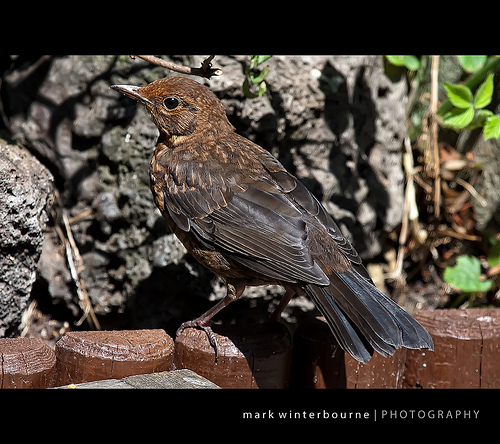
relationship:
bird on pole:
[103, 73, 437, 366] [182, 324, 289, 388]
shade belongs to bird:
[218, 308, 330, 386] [103, 73, 437, 366]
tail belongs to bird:
[309, 277, 436, 356] [103, 73, 437, 366]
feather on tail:
[344, 335, 447, 364] [309, 277, 436, 356]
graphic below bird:
[240, 401, 489, 433] [103, 73, 437, 366]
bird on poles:
[103, 73, 437, 366] [2, 302, 499, 384]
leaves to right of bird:
[386, 59, 499, 140] [103, 73, 437, 366]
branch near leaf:
[133, 54, 223, 78] [249, 54, 272, 94]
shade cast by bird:
[218, 308, 330, 386] [103, 73, 437, 366]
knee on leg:
[225, 281, 247, 301] [170, 288, 245, 356]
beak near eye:
[110, 81, 143, 97] [162, 98, 183, 109]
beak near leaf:
[110, 81, 143, 97] [249, 54, 272, 94]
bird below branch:
[103, 73, 437, 366] [133, 54, 223, 78]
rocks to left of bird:
[0, 157, 48, 332] [103, 73, 437, 366]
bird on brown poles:
[103, 73, 437, 366] [2, 302, 499, 384]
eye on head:
[162, 98, 183, 109] [109, 76, 235, 137]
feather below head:
[344, 335, 447, 364] [109, 76, 235, 137]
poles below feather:
[2, 302, 499, 384] [344, 335, 447, 364]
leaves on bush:
[386, 59, 499, 140] [403, 147, 494, 294]